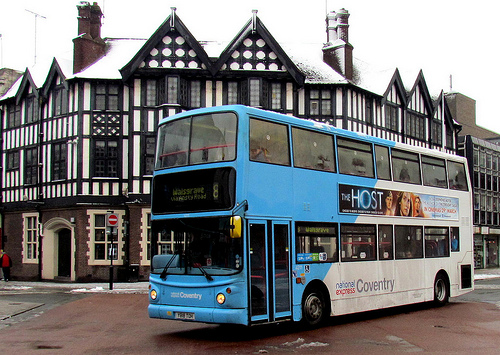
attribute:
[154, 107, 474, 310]
bus — blue, double decker, white, moving, half white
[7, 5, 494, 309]
house — brown, 2 story, white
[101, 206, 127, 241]
sign — red, round, white, do not enter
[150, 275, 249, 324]
headlights — white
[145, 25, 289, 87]
gables — black, white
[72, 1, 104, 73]
chimney — red brick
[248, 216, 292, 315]
door — double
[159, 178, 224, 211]
electric sign — for destination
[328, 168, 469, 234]
ad — on bus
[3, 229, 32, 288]
person — standing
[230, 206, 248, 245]
mirror — yellow